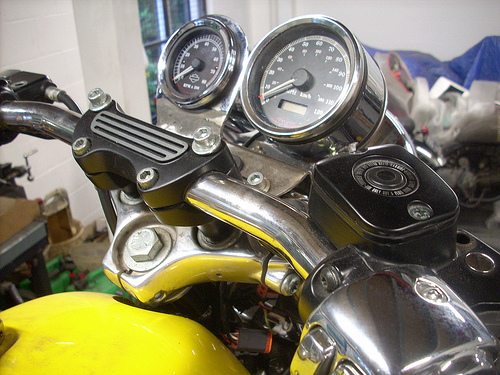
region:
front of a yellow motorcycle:
[5, 11, 482, 373]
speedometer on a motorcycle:
[235, 12, 387, 162]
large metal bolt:
[116, 212, 173, 273]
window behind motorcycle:
[132, 2, 202, 122]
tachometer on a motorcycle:
[156, 12, 236, 117]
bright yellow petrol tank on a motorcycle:
[3, 286, 248, 373]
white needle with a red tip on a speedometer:
[250, 69, 304, 106]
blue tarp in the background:
[366, 22, 499, 97]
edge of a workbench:
[0, 142, 55, 312]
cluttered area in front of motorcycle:
[377, 51, 497, 217]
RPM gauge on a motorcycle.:
[148, 12, 248, 119]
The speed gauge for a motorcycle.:
[229, 8, 399, 195]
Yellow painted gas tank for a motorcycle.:
[0, 296, 280, 374]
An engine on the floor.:
[366, 80, 498, 211]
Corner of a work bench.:
[0, 153, 70, 307]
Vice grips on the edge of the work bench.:
[1, 138, 53, 210]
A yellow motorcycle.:
[0, 22, 496, 372]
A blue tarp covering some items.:
[333, 21, 498, 107]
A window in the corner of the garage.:
[111, 0, 211, 131]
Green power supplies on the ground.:
[12, 238, 143, 318]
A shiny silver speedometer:
[238, 9, 390, 168]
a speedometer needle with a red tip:
[249, 59, 321, 119]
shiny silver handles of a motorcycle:
[0, 35, 494, 370]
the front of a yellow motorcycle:
[3, 196, 280, 366]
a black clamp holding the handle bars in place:
[52, 78, 260, 228]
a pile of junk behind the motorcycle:
[265, 18, 497, 213]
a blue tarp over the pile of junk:
[263, 17, 499, 93]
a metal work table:
[0, 188, 75, 288]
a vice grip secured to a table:
[1, 142, 46, 216]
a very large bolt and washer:
[109, 215, 188, 290]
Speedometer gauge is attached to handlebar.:
[237, 13, 375, 163]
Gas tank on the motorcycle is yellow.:
[1, 290, 245, 373]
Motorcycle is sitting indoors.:
[1, 2, 498, 304]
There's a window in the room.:
[115, 3, 262, 164]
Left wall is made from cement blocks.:
[3, 2, 123, 285]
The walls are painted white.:
[3, 5, 495, 273]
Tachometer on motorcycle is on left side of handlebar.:
[132, 10, 246, 117]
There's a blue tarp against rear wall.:
[350, 32, 498, 107]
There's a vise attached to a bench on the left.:
[0, 141, 65, 227]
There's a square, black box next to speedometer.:
[288, 135, 472, 270]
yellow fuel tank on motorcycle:
[0, 280, 225, 373]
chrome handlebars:
[2, 82, 479, 373]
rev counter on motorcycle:
[155, 3, 235, 117]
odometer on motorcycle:
[236, 12, 386, 143]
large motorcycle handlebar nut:
[105, 220, 183, 268]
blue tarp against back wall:
[355, 30, 493, 105]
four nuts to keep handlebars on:
[63, 82, 243, 209]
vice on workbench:
[2, 141, 44, 188]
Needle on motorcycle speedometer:
[257, 65, 328, 106]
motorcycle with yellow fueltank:
[1, 9, 380, 363]